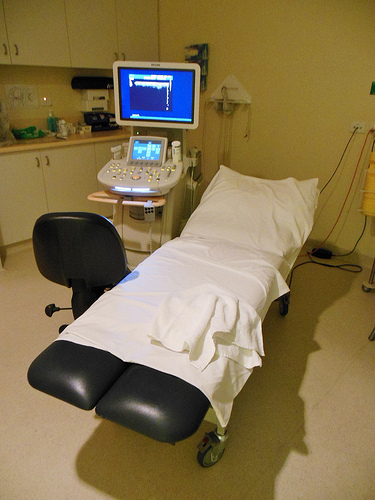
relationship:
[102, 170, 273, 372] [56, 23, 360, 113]
bed in hospital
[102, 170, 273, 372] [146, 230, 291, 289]
bed has blankets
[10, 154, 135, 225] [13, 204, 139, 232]
cupboards at bottom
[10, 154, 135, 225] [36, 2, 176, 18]
cupboards at top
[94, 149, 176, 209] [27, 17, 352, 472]
medical equipment in photo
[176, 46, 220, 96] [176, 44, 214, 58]
gloves in box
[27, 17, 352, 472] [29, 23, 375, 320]
photo has office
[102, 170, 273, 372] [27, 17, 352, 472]
bed in photo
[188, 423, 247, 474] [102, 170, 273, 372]
wheels on bed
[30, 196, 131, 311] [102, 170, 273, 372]
chair beside bed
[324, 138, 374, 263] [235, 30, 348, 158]
cords hanging wall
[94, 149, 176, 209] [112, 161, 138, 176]
medical equipment have dials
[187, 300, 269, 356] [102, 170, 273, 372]
towel on bed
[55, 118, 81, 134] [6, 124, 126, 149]
objects on countertop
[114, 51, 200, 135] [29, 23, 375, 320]
monitor in office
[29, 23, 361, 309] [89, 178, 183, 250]
office has table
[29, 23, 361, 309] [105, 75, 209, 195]
office has computer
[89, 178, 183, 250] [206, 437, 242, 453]
table has wheel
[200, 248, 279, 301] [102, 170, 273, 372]
blankets on bed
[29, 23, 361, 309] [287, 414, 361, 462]
office has floor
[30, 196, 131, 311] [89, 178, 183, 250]
chair near table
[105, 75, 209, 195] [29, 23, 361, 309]
computer in office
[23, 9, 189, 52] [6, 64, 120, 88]
cabinets on side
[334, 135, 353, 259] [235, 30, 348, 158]
wires on wall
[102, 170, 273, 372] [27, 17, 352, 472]
table in photo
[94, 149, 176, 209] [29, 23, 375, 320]
medical equipment in office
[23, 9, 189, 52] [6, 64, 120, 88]
cabinets by side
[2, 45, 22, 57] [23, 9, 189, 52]
handles on cabinets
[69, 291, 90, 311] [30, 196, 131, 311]
knob on chair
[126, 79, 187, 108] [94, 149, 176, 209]
screen on medical equipment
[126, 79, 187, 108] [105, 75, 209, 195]
screen on computer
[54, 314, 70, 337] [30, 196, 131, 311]
wheel on chair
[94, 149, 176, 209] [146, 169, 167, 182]
medical equipment with light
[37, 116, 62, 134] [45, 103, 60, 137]
sanitizer in bottle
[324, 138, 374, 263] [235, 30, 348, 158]
cords on wall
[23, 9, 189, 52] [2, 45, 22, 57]
cabinets have handles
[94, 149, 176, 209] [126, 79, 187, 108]
medical equipment has screen